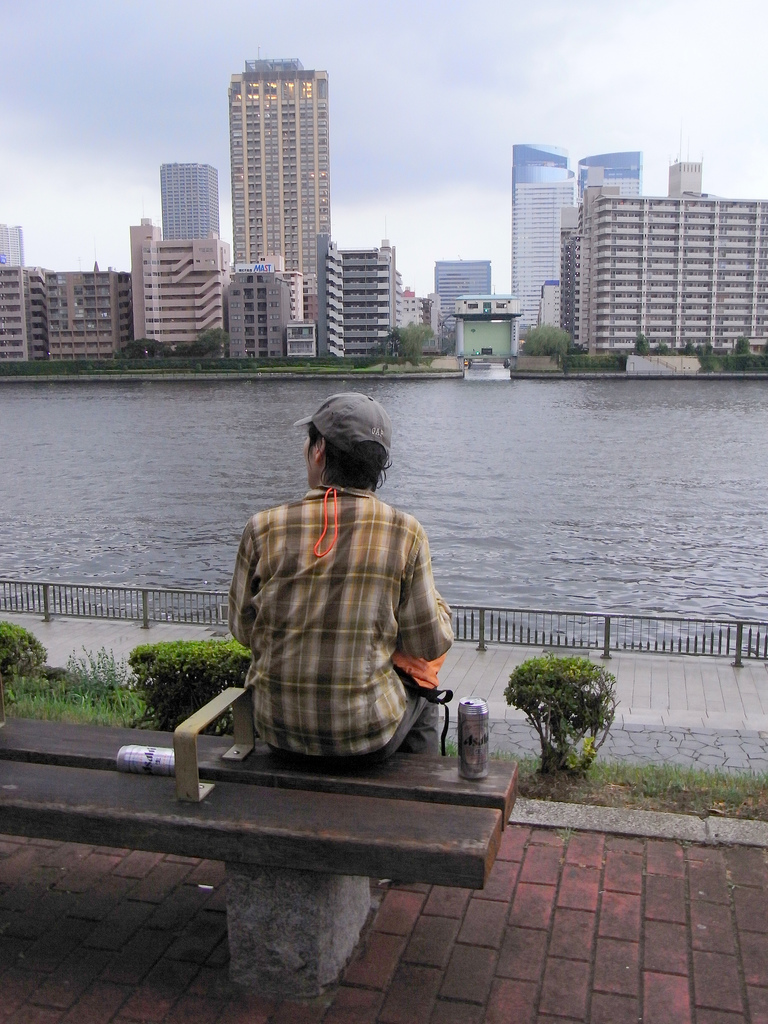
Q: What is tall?
A: Buildings.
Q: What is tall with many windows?
A: Buildings.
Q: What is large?
A: Body of water.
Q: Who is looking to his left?
A: Man on bench.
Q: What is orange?
A: Strap.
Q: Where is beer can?
A: Next to man on bench.